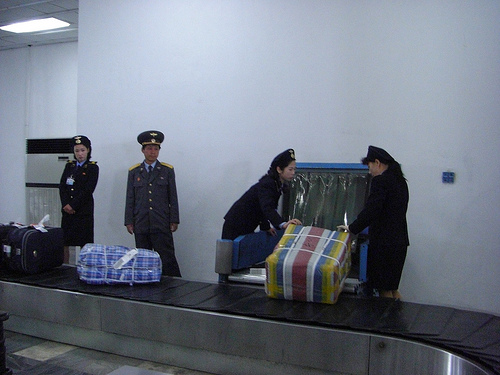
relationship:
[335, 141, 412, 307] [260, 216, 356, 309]
lady pushing on luggage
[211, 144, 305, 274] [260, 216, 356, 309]
lady pushing on luggage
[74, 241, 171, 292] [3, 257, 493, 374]
bag on conveyor belt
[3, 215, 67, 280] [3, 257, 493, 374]
bag on conveyor belt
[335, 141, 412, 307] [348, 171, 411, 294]
lady in a uniform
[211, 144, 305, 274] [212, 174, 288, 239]
lady in a uniform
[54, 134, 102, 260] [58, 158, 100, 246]
lady in a uniform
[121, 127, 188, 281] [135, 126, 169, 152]
man wearing a hat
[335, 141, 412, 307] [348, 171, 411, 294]
lady wearing a uniform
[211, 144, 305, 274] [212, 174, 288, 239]
lady wearing a uniform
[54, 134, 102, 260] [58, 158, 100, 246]
lady wearing a uniform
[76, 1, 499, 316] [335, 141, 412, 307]
wall behind lady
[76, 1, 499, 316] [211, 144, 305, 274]
wall behind lady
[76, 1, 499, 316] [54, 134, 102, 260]
wall behind lady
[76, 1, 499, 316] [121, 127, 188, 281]
wall behind man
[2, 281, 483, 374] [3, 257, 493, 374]
side of conveyor belt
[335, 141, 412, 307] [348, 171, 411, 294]
lady has a uniform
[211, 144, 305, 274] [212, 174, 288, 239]
lady has a uniform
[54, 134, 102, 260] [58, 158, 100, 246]
lady has a uniform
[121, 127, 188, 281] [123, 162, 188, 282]
man has a uniform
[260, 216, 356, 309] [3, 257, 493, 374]
bag on conveyor belt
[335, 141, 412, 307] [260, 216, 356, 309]
lady holding luggage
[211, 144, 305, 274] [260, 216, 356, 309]
lady holding luggage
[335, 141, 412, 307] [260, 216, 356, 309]
lady checking luggage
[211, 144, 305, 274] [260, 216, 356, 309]
lady checking luggage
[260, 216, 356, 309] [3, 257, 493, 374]
luggage on a conveyor belt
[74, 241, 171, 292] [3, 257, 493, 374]
bag on a conveyor belt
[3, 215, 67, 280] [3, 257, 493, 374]
bag on a conveyor belt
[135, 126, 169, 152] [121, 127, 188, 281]
hat on a man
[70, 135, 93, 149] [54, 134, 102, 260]
hat on a lady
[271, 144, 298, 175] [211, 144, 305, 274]
hat on a lady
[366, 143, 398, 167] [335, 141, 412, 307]
hat on a lady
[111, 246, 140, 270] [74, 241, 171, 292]
tag on a bag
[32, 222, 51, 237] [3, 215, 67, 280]
tag on a bag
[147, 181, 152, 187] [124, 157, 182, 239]
button on a jacket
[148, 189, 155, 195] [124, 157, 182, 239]
button on a jacket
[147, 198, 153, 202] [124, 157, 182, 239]
button on a jacket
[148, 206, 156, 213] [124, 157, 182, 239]
button on a jacket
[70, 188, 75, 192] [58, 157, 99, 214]
button on a jacket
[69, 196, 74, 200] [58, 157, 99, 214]
button on a jacket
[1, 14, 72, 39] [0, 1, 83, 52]
ceiling light on ceiling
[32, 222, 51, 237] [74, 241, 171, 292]
tag on a bag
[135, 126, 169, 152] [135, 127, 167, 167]
hat on a head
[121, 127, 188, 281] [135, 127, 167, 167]
man has a head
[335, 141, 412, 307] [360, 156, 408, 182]
lady has hair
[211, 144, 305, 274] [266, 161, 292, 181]
lady has hair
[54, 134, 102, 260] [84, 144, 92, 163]
lady has hair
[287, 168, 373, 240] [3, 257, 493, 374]
door to conveyor belt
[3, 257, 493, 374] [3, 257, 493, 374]
conveyor belt used as a conveyor belt